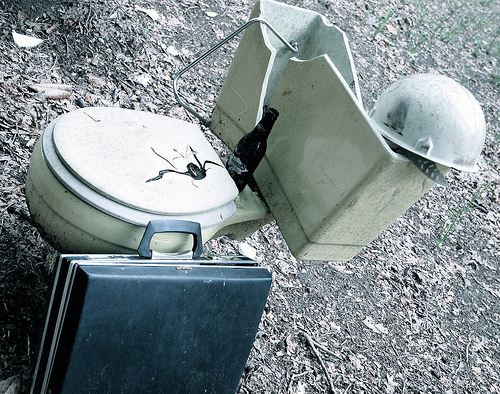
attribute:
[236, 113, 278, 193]
bottle — dark, glass, empty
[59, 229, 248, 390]
briefcase — black, square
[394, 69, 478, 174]
helmet — white, hard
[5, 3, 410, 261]
toilet — white, broken, dirty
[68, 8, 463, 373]
pile — junk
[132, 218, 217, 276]
handle — black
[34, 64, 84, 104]
leaf — dead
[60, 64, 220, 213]
lid — closed, cracked